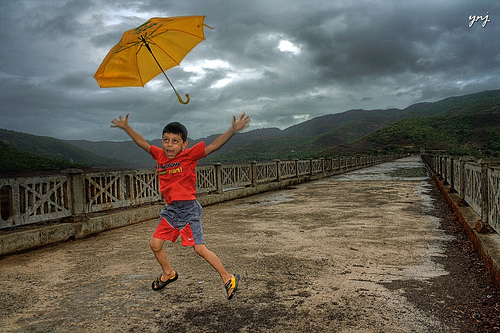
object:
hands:
[233, 112, 251, 131]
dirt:
[384, 243, 498, 327]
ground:
[0, 150, 493, 325]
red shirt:
[144, 141, 208, 206]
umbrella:
[82, 12, 224, 107]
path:
[291, 126, 457, 261]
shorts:
[152, 200, 206, 247]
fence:
[424, 151, 499, 241]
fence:
[0, 148, 412, 225]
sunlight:
[204, 73, 245, 91]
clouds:
[0, 0, 500, 143]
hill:
[322, 116, 500, 156]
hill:
[238, 107, 364, 154]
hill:
[71, 127, 284, 168]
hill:
[0, 127, 137, 176]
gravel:
[415, 248, 484, 330]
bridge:
[1, 143, 499, 330]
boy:
[109, 111, 251, 300]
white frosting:
[219, 269, 243, 302]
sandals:
[151, 270, 179, 290]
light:
[194, 55, 259, 95]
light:
[89, 3, 139, 23]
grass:
[12, 124, 44, 159]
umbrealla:
[88, 9, 212, 109]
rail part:
[460, 181, 473, 197]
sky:
[0, 0, 495, 172]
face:
[161, 130, 180, 157]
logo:
[156, 162, 183, 176]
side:
[16, 212, 152, 246]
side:
[424, 155, 495, 331]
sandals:
[223, 275, 236, 299]